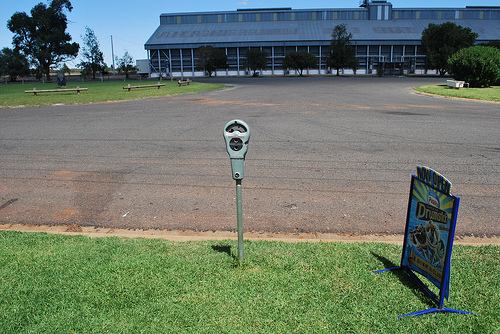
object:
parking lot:
[0, 105, 500, 222]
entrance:
[377, 60, 404, 76]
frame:
[391, 166, 462, 302]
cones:
[391, 52, 451, 76]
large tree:
[418, 22, 471, 76]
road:
[0, 77, 499, 238]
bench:
[445, 78, 465, 89]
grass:
[413, 82, 499, 100]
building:
[142, 0, 500, 74]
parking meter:
[218, 119, 252, 176]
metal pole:
[220, 118, 250, 277]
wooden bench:
[120, 83, 167, 91]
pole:
[234, 179, 245, 259]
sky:
[0, 0, 500, 27]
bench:
[176, 75, 192, 86]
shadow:
[211, 242, 238, 263]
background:
[403, 178, 453, 287]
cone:
[404, 221, 445, 266]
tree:
[325, 22, 356, 76]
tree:
[281, 50, 317, 77]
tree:
[194, 43, 230, 76]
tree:
[420, 20, 479, 76]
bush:
[442, 42, 500, 87]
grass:
[0, 80, 234, 106]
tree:
[244, 46, 270, 77]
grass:
[0, 229, 500, 334]